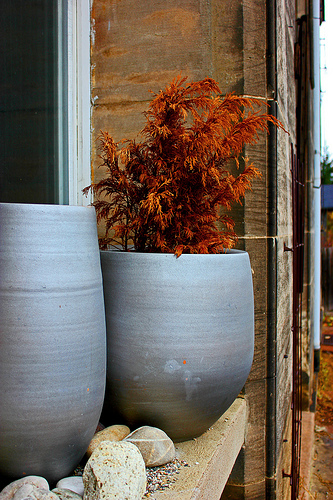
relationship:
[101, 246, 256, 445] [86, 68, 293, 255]
planter with bush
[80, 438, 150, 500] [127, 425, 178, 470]
rock by stone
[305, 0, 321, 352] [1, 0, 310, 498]
pipe on building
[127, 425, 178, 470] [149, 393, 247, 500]
stone on ledge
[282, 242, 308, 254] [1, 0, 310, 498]
nail on building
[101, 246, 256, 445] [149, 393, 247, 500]
planter on ledge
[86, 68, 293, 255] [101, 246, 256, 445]
bush in planter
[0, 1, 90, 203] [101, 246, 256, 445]
window by planter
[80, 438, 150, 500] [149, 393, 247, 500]
rock on ledge